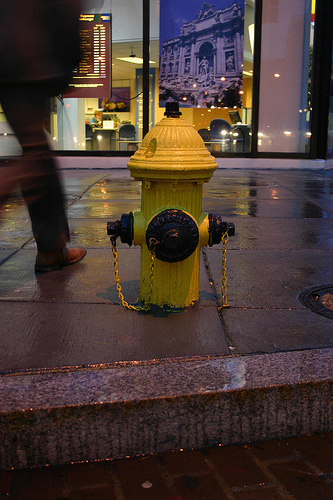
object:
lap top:
[228, 110, 242, 124]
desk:
[232, 123, 251, 152]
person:
[90, 109, 102, 127]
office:
[46, 0, 255, 154]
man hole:
[301, 276, 332, 320]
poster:
[157, 1, 242, 110]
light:
[283, 129, 292, 136]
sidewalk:
[220, 169, 277, 220]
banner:
[159, 0, 243, 107]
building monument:
[158, 0, 243, 104]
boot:
[33, 238, 86, 272]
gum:
[141, 480, 153, 489]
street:
[0, 152, 330, 494]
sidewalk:
[0, 163, 329, 378]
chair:
[110, 124, 136, 151]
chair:
[84, 122, 94, 149]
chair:
[195, 128, 211, 149]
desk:
[94, 127, 118, 150]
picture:
[159, 0, 242, 109]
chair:
[210, 118, 245, 154]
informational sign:
[69, 14, 109, 96]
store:
[67, 15, 307, 155]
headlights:
[221, 129, 227, 135]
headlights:
[229, 131, 232, 134]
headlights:
[232, 131, 239, 137]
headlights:
[282, 129, 292, 137]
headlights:
[305, 131, 312, 137]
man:
[0, 0, 87, 271]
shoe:
[33, 246, 87, 272]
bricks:
[0, 432, 332, 499]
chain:
[109, 233, 156, 313]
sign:
[55, 11, 112, 90]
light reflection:
[220, 128, 228, 136]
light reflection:
[248, 131, 254, 138]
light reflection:
[258, 131, 268, 139]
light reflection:
[274, 72, 280, 79]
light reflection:
[305, 132, 311, 138]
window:
[41, 0, 257, 155]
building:
[2, 0, 330, 168]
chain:
[219, 232, 230, 309]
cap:
[162, 101, 182, 120]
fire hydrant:
[106, 89, 236, 309]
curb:
[1, 347, 332, 468]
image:
[0, 0, 86, 275]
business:
[91, 20, 106, 79]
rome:
[156, 9, 247, 105]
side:
[103, 99, 236, 312]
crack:
[201, 247, 220, 307]